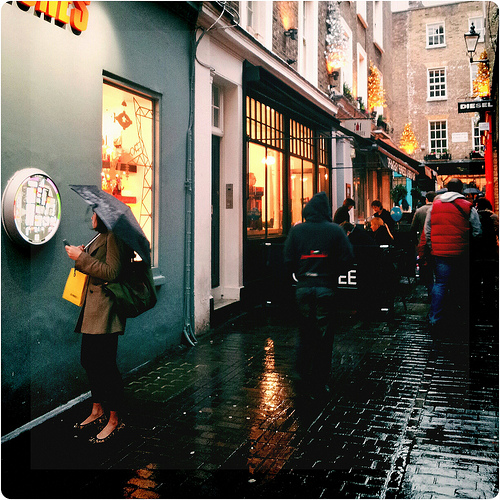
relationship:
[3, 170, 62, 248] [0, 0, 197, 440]
map on building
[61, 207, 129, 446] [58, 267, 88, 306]
woman holding bag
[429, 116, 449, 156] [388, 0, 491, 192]
window on building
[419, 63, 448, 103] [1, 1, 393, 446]
window on building